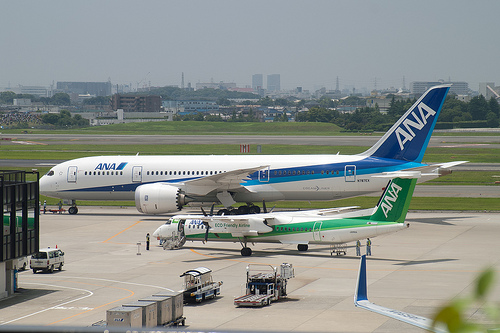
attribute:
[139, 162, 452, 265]
plane — green, white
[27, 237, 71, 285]
van — white, parked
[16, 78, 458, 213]
plane — blue, white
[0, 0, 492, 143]
background — dark gray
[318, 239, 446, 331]
airplane — blue, white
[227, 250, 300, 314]
luggage cart — silver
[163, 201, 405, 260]
green strip — white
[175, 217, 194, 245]
door — open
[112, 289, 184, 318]
luggage carts — chained